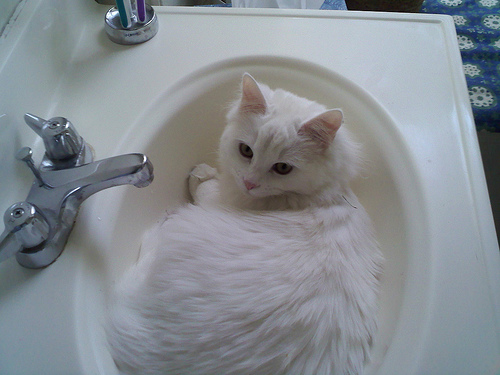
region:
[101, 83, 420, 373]
Cat sitting in a sink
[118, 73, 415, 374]
White long-haired cat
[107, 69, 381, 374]
Cats staying cool in a sink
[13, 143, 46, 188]
Plunger for the drain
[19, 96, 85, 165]
Cold water valve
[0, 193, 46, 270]
Hot water valve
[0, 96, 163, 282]
Faucet on a bathroom sink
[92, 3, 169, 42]
Toothbrush holder sitting on a sink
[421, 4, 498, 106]
Throw rug on the bathroom floor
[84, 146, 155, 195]
Water spigot for bathroom sink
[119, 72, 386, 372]
A fluffy white cat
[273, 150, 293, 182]
A cat's yellow eye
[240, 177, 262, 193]
A cat's tiny pink nose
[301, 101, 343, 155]
The pink ear of a cat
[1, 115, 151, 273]
The silver faucet of a sink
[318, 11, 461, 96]
A white sink counter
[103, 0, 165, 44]
A toothbrush holder with toothbrushes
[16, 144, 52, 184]
The raised stopper on a sink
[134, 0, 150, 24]
The purple handle of a toothbrush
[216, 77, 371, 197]
face of long haired white cat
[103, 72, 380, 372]
long haired white cat in bathroom sink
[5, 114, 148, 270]
chrome faucet on the white sink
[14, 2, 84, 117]
part of attached back splash on the sink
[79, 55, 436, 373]
bowl of the sink holding the white kitty.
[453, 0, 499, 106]
portion of the blue bath mat with white and black designs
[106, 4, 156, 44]
chrome toothbrush holder on back of the sink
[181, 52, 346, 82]
decorative ridge around the rim of the bowl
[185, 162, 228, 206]
cat's paw resting on the side of the sink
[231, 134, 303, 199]
face of the cat looking back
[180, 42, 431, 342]
Cat in the sink.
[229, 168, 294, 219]
Pink nose on the cat.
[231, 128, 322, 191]
eyes of the cat.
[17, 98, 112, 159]
Handle on the faucet.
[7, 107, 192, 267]
Faucet on the sink.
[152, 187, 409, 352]
White fur on the cat.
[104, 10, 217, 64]
Toothbrush holder on the sink.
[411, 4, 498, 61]
Carpet on the floor.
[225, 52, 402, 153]
Ears on the cat.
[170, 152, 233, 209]
paw of the cat.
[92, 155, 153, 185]
front part of faucet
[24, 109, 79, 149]
knob on the sink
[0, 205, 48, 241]
another knob on sink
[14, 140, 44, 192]
stopper part of sink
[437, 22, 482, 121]
edge of the sink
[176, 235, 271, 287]
fur on the cat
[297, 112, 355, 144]
ear on the cat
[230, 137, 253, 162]
eye on the cat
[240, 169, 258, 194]
nose on the cat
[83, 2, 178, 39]
a silver toothbrush holder